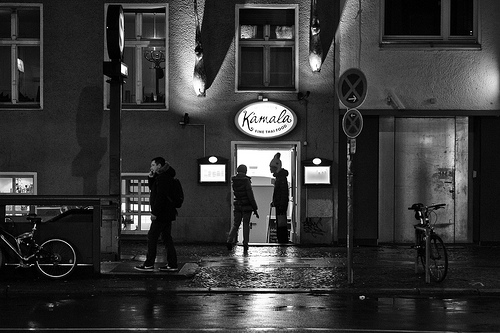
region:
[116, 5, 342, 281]
people standing in front of restaurant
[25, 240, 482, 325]
wet sidewalk and street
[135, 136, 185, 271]
standing man using cellphone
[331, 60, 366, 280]
pole with circular signs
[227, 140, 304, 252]
women standing by lit doorway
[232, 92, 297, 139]
lit oval sign with script and printing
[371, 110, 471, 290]
parked bike near doorway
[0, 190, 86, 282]
bicycle on side of partition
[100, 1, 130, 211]
lighted sign on tall pole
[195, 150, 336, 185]
lighted panels on side of doorway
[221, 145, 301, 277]
People standing in the doorway.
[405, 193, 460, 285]
A bicycle parked in front of building.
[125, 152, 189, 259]
A man talking on cellphone.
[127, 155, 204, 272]
A man walking on the sidewalk.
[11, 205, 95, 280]
A bike parked by the stairway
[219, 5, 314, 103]
Window on the buildng.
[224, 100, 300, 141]
A sign in front of the store.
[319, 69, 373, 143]
A sign with an "X" on it.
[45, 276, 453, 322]
The streets are wet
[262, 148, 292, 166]
The person is wearing a cap.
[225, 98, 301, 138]
sign on a building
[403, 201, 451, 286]
bike in front of a building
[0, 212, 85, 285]
bike in front of a building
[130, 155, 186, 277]
person on the sidewalk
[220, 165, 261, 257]
person on the sidewalk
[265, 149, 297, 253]
person on the sidewalk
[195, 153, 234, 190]
sign on a building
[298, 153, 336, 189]
sign on a building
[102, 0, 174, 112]
window on a building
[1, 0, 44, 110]
window on a building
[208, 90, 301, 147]
the sign is white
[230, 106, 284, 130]
black letters on sign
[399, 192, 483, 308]
the bicycle is parked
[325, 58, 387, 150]
sign on top of other sign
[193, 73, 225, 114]
light on the building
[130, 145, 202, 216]
man is talking on phone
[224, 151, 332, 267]
people standing in front of door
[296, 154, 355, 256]
screen is lit up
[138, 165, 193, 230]
man wearing a jacket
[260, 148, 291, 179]
person wearing a hat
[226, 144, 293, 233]
two people standing in doorwat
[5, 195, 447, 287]
two bicycles on sidewalk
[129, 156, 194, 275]
man walking down sidewalk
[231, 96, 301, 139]
lit up sign above doorway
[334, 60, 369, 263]
sign post with two signs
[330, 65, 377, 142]
two signs with xes on them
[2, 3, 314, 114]
three windows of top floor of building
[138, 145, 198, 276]
man walking wearing backpack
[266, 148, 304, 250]
person in doorway wearing knit hat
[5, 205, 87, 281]
bicycle leaning against wall